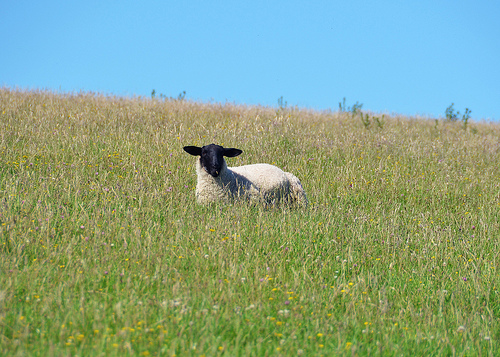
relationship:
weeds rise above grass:
[6, 77, 498, 132] [0, 121, 496, 353]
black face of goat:
[199, 143, 224, 177] [179, 135, 311, 215]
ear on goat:
[182, 145, 202, 157] [181, 143, 309, 210]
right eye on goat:
[201, 147, 209, 154] [181, 143, 309, 210]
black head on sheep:
[174, 138, 244, 180] [168, 123, 324, 213]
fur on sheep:
[188, 166, 309, 216] [174, 131, 312, 217]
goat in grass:
[181, 143, 309, 210] [0, 87, 499, 354]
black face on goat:
[199, 143, 224, 177] [181, 143, 309, 210]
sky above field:
[4, 2, 498, 114] [1, 90, 498, 355]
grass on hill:
[0, 87, 499, 354] [0, 89, 497, 350]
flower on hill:
[0, 194, 499, 357] [0, 89, 497, 350]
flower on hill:
[132, 314, 150, 331] [0, 89, 497, 350]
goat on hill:
[181, 143, 309, 210] [0, 89, 497, 350]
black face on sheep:
[199, 143, 224, 177] [176, 139, 308, 216]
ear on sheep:
[182, 145, 201, 156] [176, 139, 308, 216]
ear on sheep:
[215, 145, 242, 159] [176, 139, 308, 216]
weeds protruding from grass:
[0, 85, 498, 143] [309, 130, 450, 257]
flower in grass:
[0, 194, 499, 357] [48, 163, 120, 215]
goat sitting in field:
[181, 143, 309, 210] [1, 90, 498, 355]